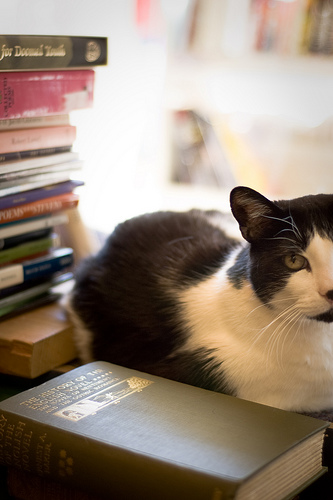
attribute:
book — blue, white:
[1, 247, 76, 294]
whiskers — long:
[244, 294, 313, 362]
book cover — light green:
[0, 359, 329, 499]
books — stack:
[0, 39, 109, 307]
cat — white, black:
[51, 173, 333, 457]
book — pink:
[0, 65, 102, 118]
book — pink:
[0, 16, 96, 155]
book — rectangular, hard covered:
[0, 359, 332, 498]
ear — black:
[223, 185, 287, 240]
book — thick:
[48, 41, 158, 70]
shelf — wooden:
[173, 18, 326, 61]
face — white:
[255, 196, 331, 321]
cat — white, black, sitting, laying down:
[64, 176, 331, 422]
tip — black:
[326, 287, 331, 297]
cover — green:
[3, 357, 331, 477]